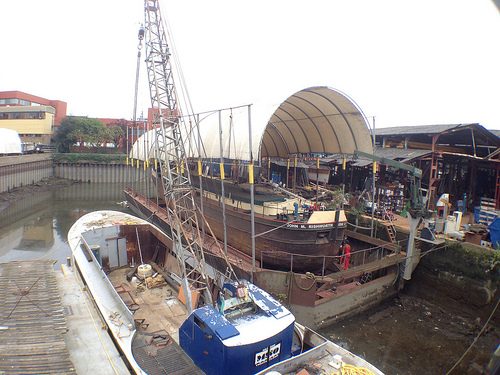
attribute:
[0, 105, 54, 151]
building — yellow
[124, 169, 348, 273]
boat — brown, white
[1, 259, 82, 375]
pier — aged, wooden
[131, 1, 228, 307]
crane — metal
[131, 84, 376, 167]
canopy — arched, white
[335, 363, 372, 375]
rope — yellow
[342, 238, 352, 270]
person — wearing red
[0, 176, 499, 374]
water — calm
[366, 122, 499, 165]
roof — metal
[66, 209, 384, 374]
boat — white, blue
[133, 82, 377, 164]
dome — large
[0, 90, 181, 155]
buildings — red, brick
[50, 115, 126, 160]
group of trees — distant, small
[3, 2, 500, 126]
sky — cloudy, white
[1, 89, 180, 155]
building — distant, red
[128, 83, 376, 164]
roof — white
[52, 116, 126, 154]
trees — green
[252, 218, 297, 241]
rope — attached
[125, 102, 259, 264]
bracing — metal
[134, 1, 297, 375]
crane — blue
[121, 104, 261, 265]
rods — metal